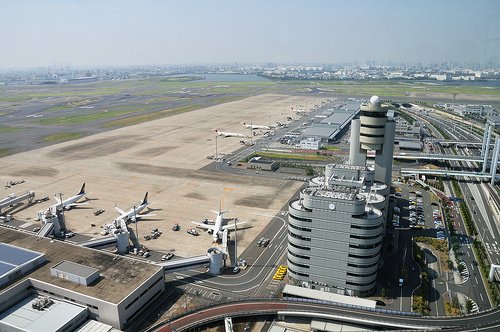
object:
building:
[0, 217, 167, 330]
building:
[348, 92, 395, 244]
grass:
[138, 87, 176, 96]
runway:
[174, 230, 205, 241]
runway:
[448, 175, 498, 302]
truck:
[394, 275, 407, 287]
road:
[392, 167, 416, 315]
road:
[149, 295, 499, 330]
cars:
[392, 205, 402, 213]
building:
[285, 181, 385, 314]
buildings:
[385, 71, 404, 80]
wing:
[130, 212, 160, 219]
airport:
[0, 84, 497, 330]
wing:
[190, 219, 217, 230]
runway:
[0, 91, 315, 262]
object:
[356, 94, 404, 114]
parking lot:
[389, 181, 444, 236]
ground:
[0, 78, 498, 182]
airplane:
[192, 200, 247, 241]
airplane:
[100, 191, 158, 229]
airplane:
[44, 181, 89, 211]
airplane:
[240, 117, 275, 130]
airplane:
[211, 127, 252, 139]